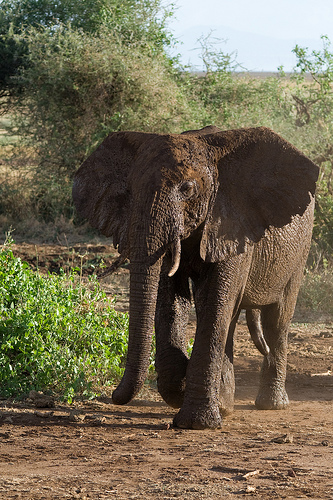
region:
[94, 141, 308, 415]
the mud is on the elephant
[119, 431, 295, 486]
the ground is brown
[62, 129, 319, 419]
the elephant is huge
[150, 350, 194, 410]
one leg is up in the air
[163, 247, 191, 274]
the tusks are short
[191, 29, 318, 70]
hills are in the background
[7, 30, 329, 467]
the elephant is in africa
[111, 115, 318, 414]
the scene is outdoors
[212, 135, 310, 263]
the ears are big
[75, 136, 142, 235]
the ear is wet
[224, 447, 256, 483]
part of a stick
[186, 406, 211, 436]
edge of a paw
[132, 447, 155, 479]
part of a floor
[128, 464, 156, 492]
part of a ground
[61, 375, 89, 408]
part of a plant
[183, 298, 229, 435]
A big rough elephant hoof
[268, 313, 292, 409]
A big rough elephant hoof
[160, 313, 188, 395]
A big rough elephant hoof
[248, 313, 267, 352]
A big fat elephant's pennis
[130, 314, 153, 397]
A big elephants tusk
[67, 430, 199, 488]
A brown muddy surface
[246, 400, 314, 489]
A brown muddy surface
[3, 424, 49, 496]
A brown muddy surface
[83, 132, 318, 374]
A big dirty brown elephant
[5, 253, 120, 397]
A small green vegitation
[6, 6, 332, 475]
A elephant in the forest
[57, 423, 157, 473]
Dirt near the elephant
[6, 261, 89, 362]
Green color plants near the elephant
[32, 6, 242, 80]
Lot of trees in the forest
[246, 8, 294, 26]
A blue color sky with clouds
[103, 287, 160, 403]
Trunk of the elephant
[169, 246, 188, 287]
Tusk of the elephant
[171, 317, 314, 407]
Legs of the elephant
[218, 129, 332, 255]
Huge ear shaped like africa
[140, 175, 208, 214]
Eye with wrinkled skin of the elephant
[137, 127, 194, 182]
the elphant has dirt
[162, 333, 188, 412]
the leg is in the air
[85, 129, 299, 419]
the elephant is moving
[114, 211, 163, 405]
the truck is hanging down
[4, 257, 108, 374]
the bush is near the elephant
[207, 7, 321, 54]
the cloud are clear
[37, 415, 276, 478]
the sand is brown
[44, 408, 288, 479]
the path is dry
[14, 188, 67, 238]
the grass is dry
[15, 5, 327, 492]
the photo is taken daytime